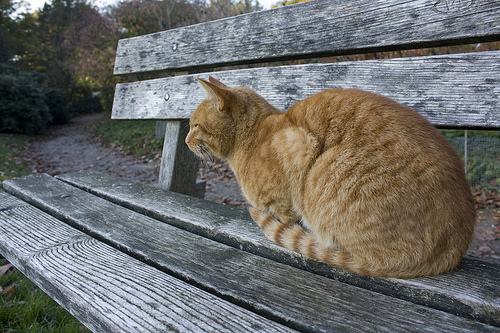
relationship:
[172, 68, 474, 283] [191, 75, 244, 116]
cat has ear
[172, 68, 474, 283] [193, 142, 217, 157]
cat has whisker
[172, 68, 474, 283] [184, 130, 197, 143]
cat has nose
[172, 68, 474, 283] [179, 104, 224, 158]
cat has face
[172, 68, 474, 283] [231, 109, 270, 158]
cat has neck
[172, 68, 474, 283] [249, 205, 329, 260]
cat has tail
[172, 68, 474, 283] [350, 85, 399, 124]
cat has back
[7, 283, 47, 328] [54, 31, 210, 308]
grass under bench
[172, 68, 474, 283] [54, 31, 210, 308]
cat on bench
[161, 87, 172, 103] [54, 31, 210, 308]
bolt on bench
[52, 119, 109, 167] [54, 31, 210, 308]
path behind bench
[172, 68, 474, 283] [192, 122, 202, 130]
cat has eye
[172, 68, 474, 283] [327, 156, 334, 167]
cat has fur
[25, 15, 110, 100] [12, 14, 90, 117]
tree in distance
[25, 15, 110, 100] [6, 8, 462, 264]
tree in park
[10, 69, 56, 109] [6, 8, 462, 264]
bushes in park